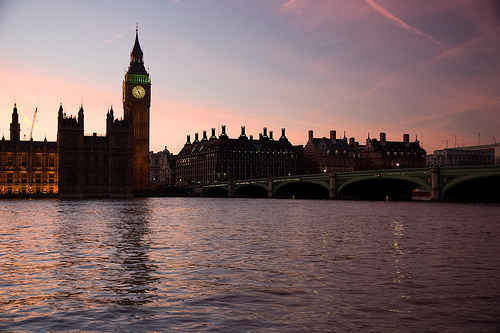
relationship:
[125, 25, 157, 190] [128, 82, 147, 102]
tower with clock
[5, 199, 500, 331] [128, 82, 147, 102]
water by clock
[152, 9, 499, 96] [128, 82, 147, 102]
sky by clock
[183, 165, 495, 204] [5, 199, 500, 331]
bridge by water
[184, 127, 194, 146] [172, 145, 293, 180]
chimney on building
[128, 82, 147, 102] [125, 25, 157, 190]
clock on tower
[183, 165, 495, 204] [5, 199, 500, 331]
bridge over water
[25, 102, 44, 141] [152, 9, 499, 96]
crane by sky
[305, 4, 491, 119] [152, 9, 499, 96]
clouds in sky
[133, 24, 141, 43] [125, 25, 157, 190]
peak on tower